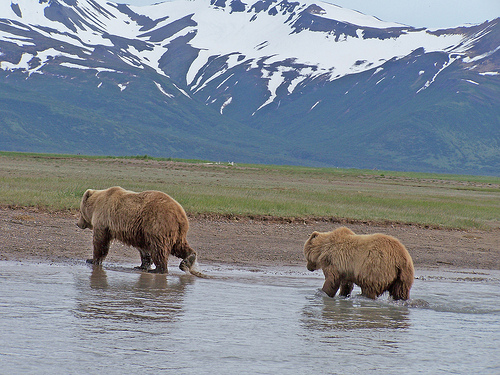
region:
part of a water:
[202, 277, 240, 298]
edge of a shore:
[238, 250, 282, 281]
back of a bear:
[363, 232, 407, 296]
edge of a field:
[231, 202, 281, 229]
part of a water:
[207, 308, 251, 343]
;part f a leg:
[133, 242, 189, 300]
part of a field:
[253, 184, 288, 216]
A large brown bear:
[68, 183, 203, 282]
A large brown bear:
[300, 222, 411, 302]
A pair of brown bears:
[61, 164, 416, 314]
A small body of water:
[1, 260, 488, 371]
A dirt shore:
[0, 206, 499, 285]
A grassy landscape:
[2, 146, 499, 224]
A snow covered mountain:
[5, 0, 499, 163]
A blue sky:
[344, 1, 493, 24]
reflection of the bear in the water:
[80, 259, 188, 331]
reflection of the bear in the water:
[294, 282, 413, 349]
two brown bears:
[71, 183, 416, 305]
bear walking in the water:
[288, 222, 453, 354]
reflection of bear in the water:
[71, 184, 199, 337]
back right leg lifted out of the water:
[72, 185, 199, 292]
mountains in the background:
[3, 16, 474, 161]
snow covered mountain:
[8, 8, 488, 136]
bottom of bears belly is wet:
[68, 186, 210, 283]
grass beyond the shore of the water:
[4, 162, 487, 276]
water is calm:
[18, 295, 306, 367]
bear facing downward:
[298, 223, 417, 308]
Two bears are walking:
[43, 155, 460, 321]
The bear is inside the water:
[279, 220, 415, 305]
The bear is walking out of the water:
[54, 185, 202, 273]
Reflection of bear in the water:
[49, 252, 178, 350]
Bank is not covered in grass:
[190, 192, 363, 278]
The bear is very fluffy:
[76, 182, 199, 272]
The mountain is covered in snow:
[56, 27, 420, 100]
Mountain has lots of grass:
[394, 87, 494, 171]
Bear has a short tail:
[162, 197, 192, 238]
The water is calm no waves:
[180, 312, 297, 372]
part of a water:
[325, 290, 370, 352]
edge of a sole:
[183, 259, 198, 273]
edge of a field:
[216, 178, 278, 245]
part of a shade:
[317, 310, 345, 337]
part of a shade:
[217, 182, 240, 204]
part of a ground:
[226, 225, 271, 265]